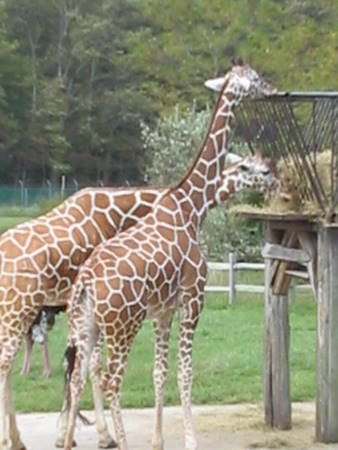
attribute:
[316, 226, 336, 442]
wood — gray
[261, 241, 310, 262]
wood — gray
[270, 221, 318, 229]
wood — gray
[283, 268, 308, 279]
wood — gray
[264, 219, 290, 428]
wood — gray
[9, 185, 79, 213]
fence — green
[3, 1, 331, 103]
forest — lush, green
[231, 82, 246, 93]
spots — brown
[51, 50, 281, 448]
giraffes — eating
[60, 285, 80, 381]
tail — long, bushy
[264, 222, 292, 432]
beam — long, wooden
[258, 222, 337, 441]
wooden legs — brown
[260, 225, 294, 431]
pillar — long, wooden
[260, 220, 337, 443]
wood — gray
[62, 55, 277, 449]
giraffe — standing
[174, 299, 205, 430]
leg — white, brown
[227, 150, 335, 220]
hay — gold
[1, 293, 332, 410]
grass — green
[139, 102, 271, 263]
tree — green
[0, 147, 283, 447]
giraffe — eating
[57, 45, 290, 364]
giraffes — fenced in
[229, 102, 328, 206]
bars — brown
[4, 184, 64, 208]
fence — green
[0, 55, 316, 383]
giraffes — eating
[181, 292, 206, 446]
leg — long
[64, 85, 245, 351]
giraffe — eating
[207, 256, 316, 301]
fence — short, wooden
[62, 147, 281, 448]
giraffe — tall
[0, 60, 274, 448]
giraffe — tall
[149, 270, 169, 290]
spot — brown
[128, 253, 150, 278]
spot — brown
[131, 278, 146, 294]
spot — brown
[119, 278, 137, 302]
spot — brown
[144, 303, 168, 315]
spot — brown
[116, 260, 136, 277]
spot — brown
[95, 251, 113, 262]
spot — brown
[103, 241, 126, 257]
spot — brown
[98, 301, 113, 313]
spot — brown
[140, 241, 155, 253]
spot — brown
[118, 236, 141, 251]
spot — brown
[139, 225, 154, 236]
spot — brown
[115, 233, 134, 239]
spot — brown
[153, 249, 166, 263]
spot — brown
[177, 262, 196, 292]
spot — brown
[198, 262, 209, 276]
spot — brown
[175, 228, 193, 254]
spot — brown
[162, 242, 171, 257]
spot — brown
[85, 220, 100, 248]
spot — brown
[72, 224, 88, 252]
spot — brown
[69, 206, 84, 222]
spot — brown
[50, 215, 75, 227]
spot — brown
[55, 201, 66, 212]
spot — brown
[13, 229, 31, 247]
spot — brown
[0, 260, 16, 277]
spot — brown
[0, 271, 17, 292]
spot — brown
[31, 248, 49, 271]
spot — brown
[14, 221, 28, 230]
spot — brown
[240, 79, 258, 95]
ear — white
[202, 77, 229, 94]
ear — white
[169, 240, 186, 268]
spot — brown